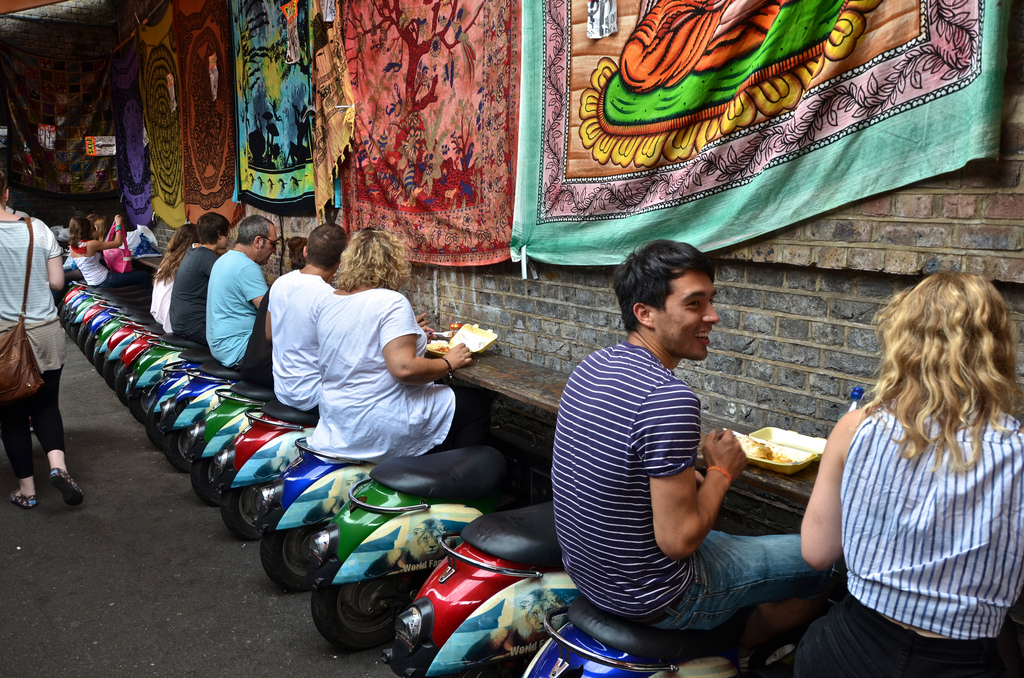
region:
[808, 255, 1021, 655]
Blonde woman is wearing a blue striped shirt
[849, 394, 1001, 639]
The blue stripes are vertical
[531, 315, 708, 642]
The blue stripes are horizontal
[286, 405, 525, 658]
The chair is a moped seat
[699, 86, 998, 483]
The wall is made of brick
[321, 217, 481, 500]
The woman is wearing a white shirt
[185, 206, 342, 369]
The man is wearing a blue tshirt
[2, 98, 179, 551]
The woman is wearing a brown leather purse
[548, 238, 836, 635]
a person is sitting down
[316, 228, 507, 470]
a person is sitting down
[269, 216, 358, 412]
a person is sitting down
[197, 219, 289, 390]
a person is sitting down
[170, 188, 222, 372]
a person is sitting down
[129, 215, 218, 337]
a person is sitting down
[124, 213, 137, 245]
a person is sitting down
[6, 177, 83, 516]
a person is standing up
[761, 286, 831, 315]
a brick in a wall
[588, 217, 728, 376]
the head of a man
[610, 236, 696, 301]
the hair of a man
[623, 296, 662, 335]
the ear of a man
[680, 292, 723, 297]
the eyebrows of a man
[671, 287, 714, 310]
the eyes of a man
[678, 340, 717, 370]
the chin of a man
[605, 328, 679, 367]
the neck of a man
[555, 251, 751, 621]
dark blue shirt with white stripes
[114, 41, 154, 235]
a purple cloth with black circle pattern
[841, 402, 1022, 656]
sleeveless cotton blouse with verticle blue stripes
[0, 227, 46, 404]
a brown shoulder leather shoulder bag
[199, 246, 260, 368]
man wearing a soft turquoise t-shirt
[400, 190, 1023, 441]
weathered grey brick wall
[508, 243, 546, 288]
clip holding together brightly printed cloths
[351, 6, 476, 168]
red tree on a lighter red cloth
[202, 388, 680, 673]
a row of moped seats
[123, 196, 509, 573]
people sitting at a restaurant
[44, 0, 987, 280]
tapestries hanging on a wall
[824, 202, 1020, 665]
a woman wearing a striped shirt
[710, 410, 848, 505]
food on a counter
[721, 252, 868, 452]
a brick wall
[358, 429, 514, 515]
a seat on a moped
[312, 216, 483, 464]
a woman wearing a white shirt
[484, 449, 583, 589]
a motorcycle seat under the counter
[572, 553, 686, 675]
a motorcycle seat under the counter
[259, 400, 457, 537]
a motorcycle seat under the counter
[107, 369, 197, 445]
a motorcycle seat under the counter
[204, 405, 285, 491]
a motorcycle seat under the counter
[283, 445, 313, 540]
a motorcycle seat under the counter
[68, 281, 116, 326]
a motorcycle seat under the counter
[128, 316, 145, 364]
a motorcycle seat under the counter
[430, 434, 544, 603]
a bike for a seat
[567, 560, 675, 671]
a bike for a seat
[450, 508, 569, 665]
a bike for a seat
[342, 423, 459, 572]
a bike for a seat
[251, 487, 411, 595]
a bike for a seat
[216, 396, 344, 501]
a bike for a seat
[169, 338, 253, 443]
a bike for a seat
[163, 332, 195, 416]
a bike for a seat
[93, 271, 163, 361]
a bike for a seat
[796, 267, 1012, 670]
a person is sitting down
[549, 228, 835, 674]
a person is sitting down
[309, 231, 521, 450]
a person is sitting down